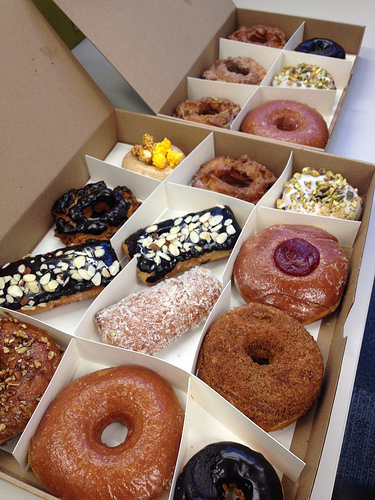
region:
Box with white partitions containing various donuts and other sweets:
[0, 108, 371, 496]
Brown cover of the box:
[0, 0, 114, 270]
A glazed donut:
[28, 362, 183, 498]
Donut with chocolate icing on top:
[174, 439, 283, 497]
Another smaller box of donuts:
[156, 8, 364, 151]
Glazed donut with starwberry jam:
[234, 222, 349, 322]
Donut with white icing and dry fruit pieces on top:
[276, 165, 362, 220]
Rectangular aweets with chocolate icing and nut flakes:
[0, 203, 241, 313]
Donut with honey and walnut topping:
[0, 319, 61, 442]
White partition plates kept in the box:
[29, 131, 359, 279]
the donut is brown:
[219, 313, 313, 403]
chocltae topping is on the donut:
[191, 444, 282, 498]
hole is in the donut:
[87, 410, 134, 453]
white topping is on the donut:
[120, 283, 184, 339]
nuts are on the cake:
[43, 253, 102, 294]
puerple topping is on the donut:
[274, 237, 320, 275]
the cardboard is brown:
[107, 14, 202, 87]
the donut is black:
[294, 36, 340, 57]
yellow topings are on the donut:
[150, 137, 178, 161]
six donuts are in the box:
[183, 13, 341, 140]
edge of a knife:
[103, 51, 126, 86]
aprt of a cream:
[199, 447, 213, 470]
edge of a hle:
[116, 409, 125, 415]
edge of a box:
[182, 434, 205, 484]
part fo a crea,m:
[215, 448, 229, 472]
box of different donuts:
[7, 169, 337, 441]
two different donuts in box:
[89, 198, 248, 357]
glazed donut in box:
[43, 357, 176, 493]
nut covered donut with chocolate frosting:
[118, 210, 241, 270]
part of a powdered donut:
[91, 298, 117, 350]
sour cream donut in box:
[193, 143, 271, 206]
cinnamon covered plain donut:
[203, 288, 311, 429]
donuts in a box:
[179, 14, 354, 184]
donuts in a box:
[176, 103, 335, 343]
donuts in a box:
[63, 191, 143, 496]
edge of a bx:
[248, 414, 279, 453]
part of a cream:
[223, 464, 239, 490]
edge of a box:
[207, 385, 225, 423]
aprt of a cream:
[213, 467, 224, 489]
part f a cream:
[227, 445, 244, 470]